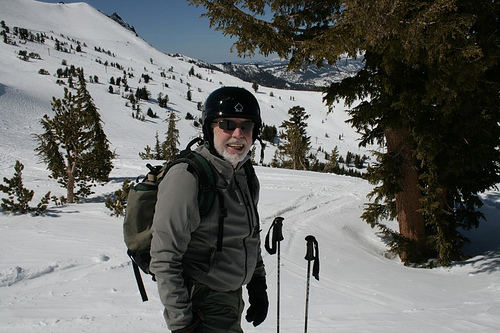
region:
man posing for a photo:
[126, 64, 336, 316]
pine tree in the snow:
[35, 55, 132, 211]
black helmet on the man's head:
[200, 82, 267, 122]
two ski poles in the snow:
[260, 194, 340, 329]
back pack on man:
[122, 140, 159, 300]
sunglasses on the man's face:
[213, 120, 260, 131]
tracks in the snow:
[290, 179, 357, 228]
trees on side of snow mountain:
[54, 30, 134, 86]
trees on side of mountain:
[72, 23, 167, 88]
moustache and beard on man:
[216, 138, 255, 163]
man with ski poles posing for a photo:
[116, 75, 338, 311]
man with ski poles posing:
[117, 78, 341, 316]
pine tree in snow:
[25, 65, 107, 221]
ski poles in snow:
[265, 207, 346, 330]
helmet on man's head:
[205, 77, 270, 118]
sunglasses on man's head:
[211, 120, 262, 136]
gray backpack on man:
[121, 151, 164, 288]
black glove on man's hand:
[245, 276, 267, 326]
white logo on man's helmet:
[232, 100, 243, 116]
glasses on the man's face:
[201, 113, 259, 161]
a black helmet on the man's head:
[200, 85, 262, 165]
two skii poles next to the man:
[266, 207, 328, 329]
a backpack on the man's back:
[115, 150, 220, 295]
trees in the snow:
[0, 28, 126, 227]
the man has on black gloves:
[246, 272, 270, 330]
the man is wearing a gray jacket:
[151, 160, 266, 331]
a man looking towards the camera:
[164, 86, 274, 331]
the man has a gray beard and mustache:
[212, 118, 252, 161]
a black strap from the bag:
[206, 185, 230, 252]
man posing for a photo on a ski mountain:
[129, 75, 329, 327]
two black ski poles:
[261, 208, 337, 327]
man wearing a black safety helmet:
[200, 85, 277, 152]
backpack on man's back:
[116, 146, 208, 284]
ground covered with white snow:
[340, 272, 473, 317]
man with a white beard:
[197, 78, 269, 176]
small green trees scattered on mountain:
[10, 13, 100, 229]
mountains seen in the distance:
[217, 55, 363, 87]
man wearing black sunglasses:
[197, 85, 266, 170]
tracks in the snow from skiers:
[280, 170, 354, 232]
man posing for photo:
[118, 91, 298, 328]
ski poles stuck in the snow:
[267, 213, 328, 330]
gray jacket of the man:
[138, 148, 270, 323]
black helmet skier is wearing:
[202, 84, 261, 118]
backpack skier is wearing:
[118, 144, 222, 289]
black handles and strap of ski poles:
[261, 209, 327, 278]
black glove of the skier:
[243, 270, 267, 325]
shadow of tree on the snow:
[433, 167, 498, 256]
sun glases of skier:
[213, 114, 260, 134]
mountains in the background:
[196, 42, 369, 96]